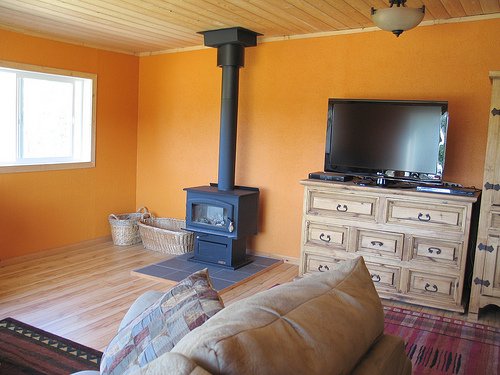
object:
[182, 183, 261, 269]
stove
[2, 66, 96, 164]
window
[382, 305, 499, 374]
rug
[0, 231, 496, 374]
floor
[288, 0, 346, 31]
panel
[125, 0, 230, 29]
panel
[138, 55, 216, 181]
orange wall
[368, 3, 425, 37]
light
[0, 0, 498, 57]
ceiling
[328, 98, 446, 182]
flat screen tv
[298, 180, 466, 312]
dresser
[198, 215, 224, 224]
wood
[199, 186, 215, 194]
stove that is black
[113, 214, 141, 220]
firewood in baskets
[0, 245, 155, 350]
floor of wood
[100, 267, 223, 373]
patchwork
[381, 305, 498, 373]
black and red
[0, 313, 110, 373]
in front of couch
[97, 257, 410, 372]
couch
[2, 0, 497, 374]
living room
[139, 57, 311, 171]
walls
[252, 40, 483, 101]
orange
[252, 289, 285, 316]
tan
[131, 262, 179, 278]
stone tiles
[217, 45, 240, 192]
large pipe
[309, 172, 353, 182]
box that is black